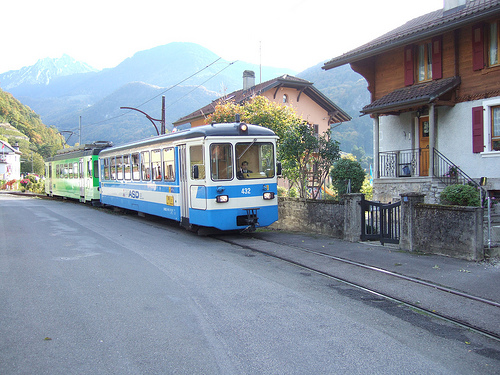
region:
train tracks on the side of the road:
[18, 233, 490, 370]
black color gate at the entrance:
[343, 189, 420, 256]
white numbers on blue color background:
[238, 186, 253, 196]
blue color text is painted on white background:
[125, 189, 142, 201]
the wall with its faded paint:
[280, 190, 477, 262]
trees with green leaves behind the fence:
[277, 124, 366, 240]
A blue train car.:
[95, 122, 279, 234]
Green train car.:
[42, 142, 109, 205]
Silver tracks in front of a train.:
[225, 225, 499, 343]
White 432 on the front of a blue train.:
[239, 186, 251, 195]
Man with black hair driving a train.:
[237, 160, 252, 178]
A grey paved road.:
[2, 192, 498, 372]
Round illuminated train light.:
[237, 121, 248, 133]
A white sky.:
[2, 0, 438, 73]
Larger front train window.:
[234, 139, 276, 181]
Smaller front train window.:
[207, 140, 232, 182]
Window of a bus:
[162, 143, 179, 179]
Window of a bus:
[149, 145, 168, 181]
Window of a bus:
[127, 148, 144, 181]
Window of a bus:
[121, 150, 133, 177]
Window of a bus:
[114, 152, 124, 178]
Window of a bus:
[108, 155, 118, 179]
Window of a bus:
[101, 155, 111, 177]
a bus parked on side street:
[91, 115, 287, 236]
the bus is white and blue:
[91, 117, 291, 244]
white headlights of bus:
[215, 191, 278, 204]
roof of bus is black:
[91, 116, 287, 235]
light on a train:
[210, 186, 230, 206]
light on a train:
[255, 190, 275, 205]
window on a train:
[230, 135, 275, 175]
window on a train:
[205, 140, 235, 185]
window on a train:
[155, 145, 175, 180]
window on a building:
[395, 45, 435, 80]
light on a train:
[236, 115, 257, 136]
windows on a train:
[113, 154, 141, 184]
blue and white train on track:
[186, 127, 288, 253]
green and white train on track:
[65, 157, 96, 207]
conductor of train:
[236, 158, 258, 183]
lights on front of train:
[209, 190, 279, 204]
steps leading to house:
[435, 170, 498, 235]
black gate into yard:
[354, 198, 405, 248]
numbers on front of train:
[237, 185, 252, 196]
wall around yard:
[289, 198, 365, 239]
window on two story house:
[395, 33, 452, 86]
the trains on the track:
[4, 117, 499, 339]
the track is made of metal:
[207, 230, 499, 339]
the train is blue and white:
[98, 113, 280, 234]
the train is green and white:
[40, 138, 112, 205]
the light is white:
[240, 123, 248, 130]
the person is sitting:
[237, 158, 252, 178]